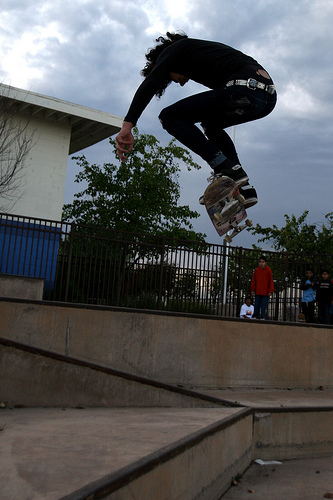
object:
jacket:
[300, 275, 317, 302]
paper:
[255, 458, 284, 466]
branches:
[0, 79, 36, 213]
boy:
[115, 36, 276, 209]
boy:
[251, 255, 274, 319]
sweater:
[315, 279, 333, 305]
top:
[240, 303, 254, 318]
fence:
[0, 211, 332, 330]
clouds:
[0, 0, 332, 250]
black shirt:
[122, 37, 274, 127]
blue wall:
[0, 216, 60, 284]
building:
[0, 81, 124, 301]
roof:
[0, 78, 126, 155]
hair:
[139, 32, 188, 101]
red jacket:
[251, 266, 273, 295]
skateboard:
[199, 175, 254, 243]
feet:
[199, 166, 258, 208]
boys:
[299, 271, 317, 322]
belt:
[227, 79, 274, 94]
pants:
[159, 79, 277, 183]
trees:
[60, 126, 206, 310]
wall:
[0, 115, 70, 229]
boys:
[314, 271, 333, 324]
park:
[1, 94, 333, 496]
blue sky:
[5, 1, 129, 103]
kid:
[240, 296, 255, 319]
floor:
[219, 444, 333, 500]